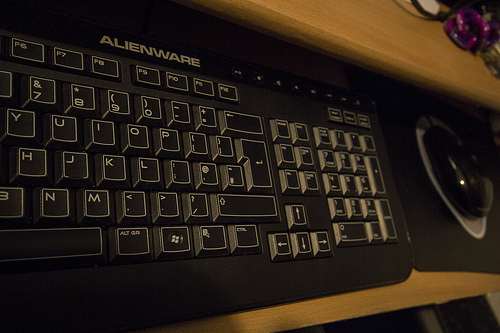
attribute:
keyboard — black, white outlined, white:
[4, 8, 420, 331]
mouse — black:
[426, 119, 486, 217]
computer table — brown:
[172, 4, 495, 331]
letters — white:
[1, 99, 199, 231]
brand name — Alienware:
[84, 24, 207, 78]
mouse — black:
[417, 103, 487, 213]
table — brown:
[201, 1, 495, 331]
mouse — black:
[417, 126, 484, 220]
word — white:
[100, 35, 209, 67]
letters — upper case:
[97, 34, 202, 70]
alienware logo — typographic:
[100, 34, 201, 69]